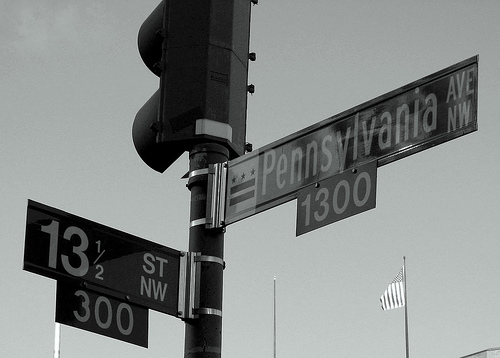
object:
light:
[136, 0, 210, 75]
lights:
[130, 88, 198, 173]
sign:
[292, 158, 377, 237]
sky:
[0, 0, 500, 358]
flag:
[377, 266, 405, 313]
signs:
[53, 277, 151, 351]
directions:
[24, 197, 183, 320]